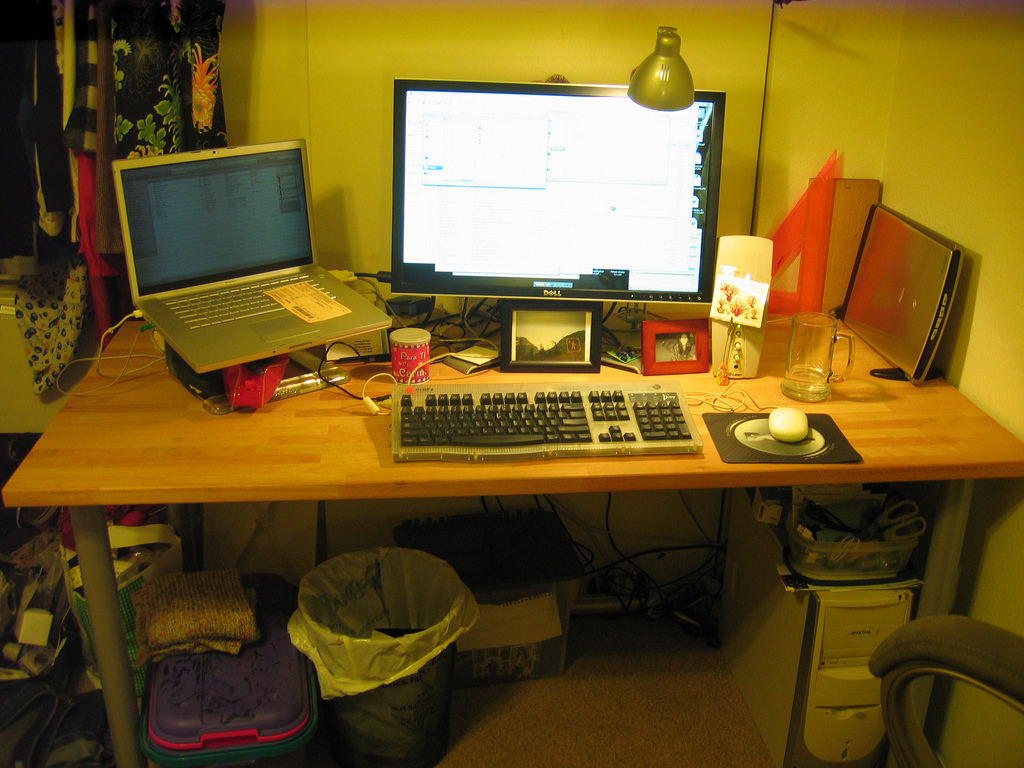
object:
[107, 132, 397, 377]
lap top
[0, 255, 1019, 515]
desk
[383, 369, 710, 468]
keyboard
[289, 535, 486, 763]
can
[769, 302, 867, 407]
glass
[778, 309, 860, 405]
mug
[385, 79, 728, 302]
monitor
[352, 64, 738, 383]
computers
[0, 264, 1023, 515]
table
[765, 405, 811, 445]
mouse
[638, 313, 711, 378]
picture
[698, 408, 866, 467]
mousepad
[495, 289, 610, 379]
mousepad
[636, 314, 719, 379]
mousepad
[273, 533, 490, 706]
bag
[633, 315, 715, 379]
photo frame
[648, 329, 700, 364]
photo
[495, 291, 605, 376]
picture frame